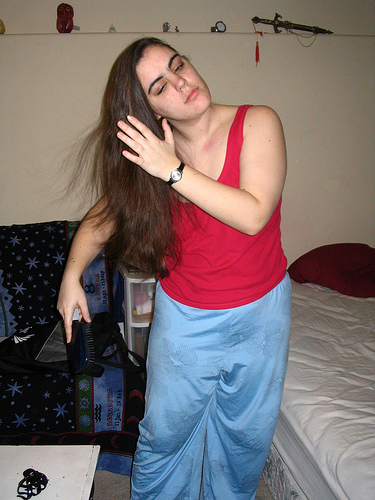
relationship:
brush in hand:
[68, 312, 102, 378] [54, 282, 92, 331]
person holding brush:
[30, 23, 346, 498] [68, 312, 102, 378]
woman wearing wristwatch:
[83, 16, 299, 296] [162, 163, 188, 184]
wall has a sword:
[307, 83, 352, 155] [237, 12, 353, 51]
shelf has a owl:
[11, 30, 43, 40] [52, 1, 84, 39]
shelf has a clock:
[11, 30, 43, 40] [206, 17, 231, 35]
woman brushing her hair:
[83, 16, 299, 296] [105, 73, 124, 99]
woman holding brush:
[83, 16, 299, 296] [68, 312, 102, 378]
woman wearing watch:
[83, 16, 299, 296] [168, 167, 184, 179]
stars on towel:
[20, 248, 47, 289] [6, 298, 14, 334]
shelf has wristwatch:
[11, 30, 43, 40] [162, 163, 188, 184]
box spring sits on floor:
[276, 464, 301, 498] [107, 477, 124, 495]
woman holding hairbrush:
[83, 16, 299, 296] [76, 352, 99, 373]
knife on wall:
[285, 19, 332, 40] [307, 83, 352, 155]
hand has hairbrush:
[54, 282, 92, 331] [76, 352, 99, 373]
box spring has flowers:
[276, 464, 301, 498] [276, 458, 284, 477]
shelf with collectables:
[11, 30, 43, 40] [0, 3, 335, 39]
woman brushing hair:
[83, 16, 299, 296] [105, 73, 124, 99]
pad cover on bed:
[300, 299, 348, 341] [299, 321, 369, 496]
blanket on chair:
[12, 224, 53, 329] [4, 220, 66, 256]